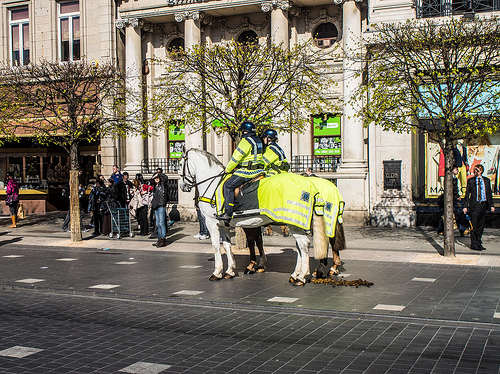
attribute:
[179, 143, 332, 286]
horse — white, mounted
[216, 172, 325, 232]
blanket — reflective, yellow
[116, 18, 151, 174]
column — ionic, stone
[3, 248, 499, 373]
street — black, white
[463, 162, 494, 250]
man — turning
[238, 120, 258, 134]
helmet — blue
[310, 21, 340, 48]
window — round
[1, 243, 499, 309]
tiles — small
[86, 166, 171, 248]
people — grouped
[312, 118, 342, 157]
poster — green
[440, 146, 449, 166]
dress — red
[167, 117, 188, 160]
poster — green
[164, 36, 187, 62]
window — round